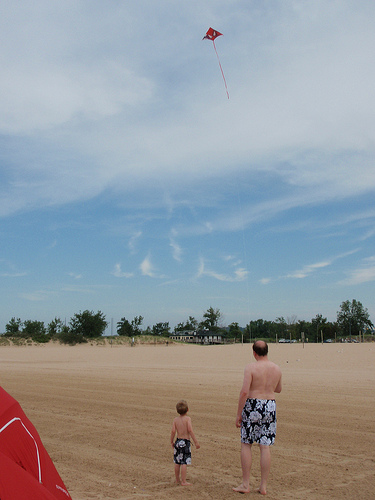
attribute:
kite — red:
[201, 24, 231, 100]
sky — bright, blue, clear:
[0, 1, 374, 336]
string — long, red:
[211, 39, 231, 101]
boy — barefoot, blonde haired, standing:
[167, 398, 202, 487]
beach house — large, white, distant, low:
[169, 327, 225, 343]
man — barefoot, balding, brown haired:
[234, 338, 283, 496]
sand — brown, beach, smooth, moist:
[0, 343, 374, 499]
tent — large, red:
[1, 387, 71, 499]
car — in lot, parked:
[278, 338, 284, 344]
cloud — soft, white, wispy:
[0, 0, 374, 215]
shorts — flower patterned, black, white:
[239, 397, 277, 446]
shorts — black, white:
[174, 438, 193, 467]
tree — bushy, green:
[74, 309, 109, 337]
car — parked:
[324, 337, 332, 345]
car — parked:
[291, 338, 298, 344]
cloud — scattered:
[109, 195, 374, 295]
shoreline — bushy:
[0, 300, 374, 344]